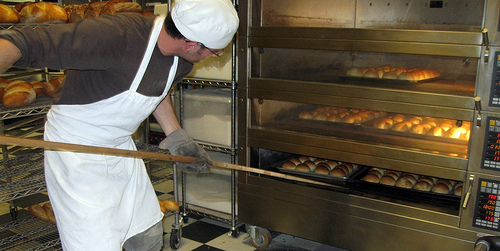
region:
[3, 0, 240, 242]
man is working in a bakery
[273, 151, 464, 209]
pans of buns cooking in oven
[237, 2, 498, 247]
large silver oven at a bakery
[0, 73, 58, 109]
freshly made bread on a metal rack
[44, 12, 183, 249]
white apron on baker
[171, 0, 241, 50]
white bakers hat on bakers head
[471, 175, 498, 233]
buttons on the front of commercial oven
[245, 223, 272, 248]
wheel on bottom of commercial oven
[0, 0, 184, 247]
metal bakers rack with bread on it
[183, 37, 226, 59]
eyeglasses on baker's head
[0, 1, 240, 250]
a man baking bread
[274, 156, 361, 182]
a pan of bread baking in the oven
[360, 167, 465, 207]
A pan of delicious looking bread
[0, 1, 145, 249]
a wire rack filled with bread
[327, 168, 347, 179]
a baked bread roll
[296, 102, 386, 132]
a pan of bread baking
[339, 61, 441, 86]
a pan of bread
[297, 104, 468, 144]
two pans of baking bread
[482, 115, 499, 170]
controls on the front of an oven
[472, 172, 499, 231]
controls on the front of an oven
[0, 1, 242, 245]
Man wearing a brown sweater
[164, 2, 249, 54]
Hat on the man's head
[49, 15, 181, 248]
Apron around the man's waist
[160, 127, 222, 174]
Glove on the man's hand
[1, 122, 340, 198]
Long stick in the man's hands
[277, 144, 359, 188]
Pan of bread in oven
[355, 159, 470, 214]
Pan of bread in oven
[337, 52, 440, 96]
Pan of bread in over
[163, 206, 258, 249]
Tile on the floor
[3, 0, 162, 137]
Bread in the background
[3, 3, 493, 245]
interior of commercial bakery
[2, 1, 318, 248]
man bent over with paddle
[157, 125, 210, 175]
glove on wood handle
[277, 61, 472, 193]
buns inside of oven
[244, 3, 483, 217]
four shelves of oven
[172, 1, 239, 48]
white cap on man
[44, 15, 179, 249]
white apron on man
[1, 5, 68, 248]
bread on metal racks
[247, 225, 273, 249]
wheel on bottom of oven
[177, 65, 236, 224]
white boxes on rack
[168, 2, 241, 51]
a white hat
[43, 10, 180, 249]
a long white apron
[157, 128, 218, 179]
a grey glove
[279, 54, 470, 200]
bread in the oven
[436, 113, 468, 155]
light in oven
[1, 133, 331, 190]
pan handle for food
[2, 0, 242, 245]
a man cooking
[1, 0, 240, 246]
the bread stand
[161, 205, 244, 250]
the checkered floor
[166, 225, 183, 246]
the wheels on stand